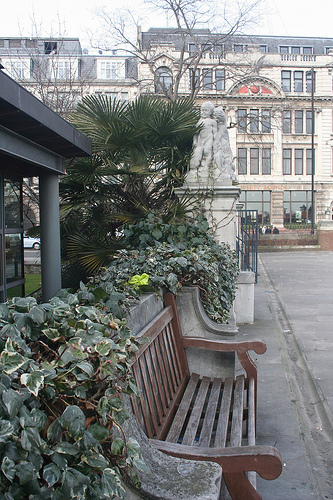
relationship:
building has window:
[2, 34, 331, 275] [17, 23, 330, 251]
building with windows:
[2, 34, 331, 275] [148, 65, 322, 181]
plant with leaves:
[80, 100, 192, 249] [129, 215, 216, 295]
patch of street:
[284, 259, 322, 308] [272, 249, 322, 387]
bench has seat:
[47, 292, 283, 487] [190, 369, 248, 450]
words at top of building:
[185, 50, 322, 61] [2, 34, 331, 275]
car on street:
[17, 231, 42, 254] [13, 240, 102, 256]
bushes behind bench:
[15, 314, 129, 496] [108, 292, 282, 494]